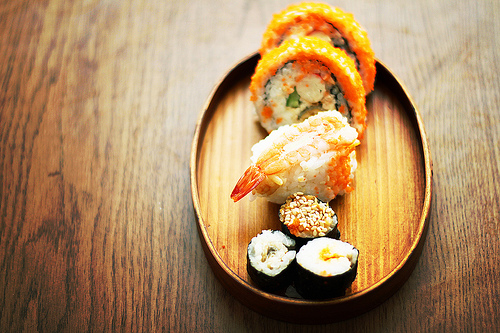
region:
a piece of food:
[287, 235, 389, 294]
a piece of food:
[245, 217, 305, 279]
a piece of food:
[278, 182, 353, 244]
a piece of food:
[227, 129, 330, 201]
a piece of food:
[303, 105, 360, 177]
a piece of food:
[251, 54, 316, 153]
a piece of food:
[308, 51, 379, 185]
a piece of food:
[237, 50, 305, 231]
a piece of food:
[284, 97, 349, 196]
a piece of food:
[233, 122, 313, 274]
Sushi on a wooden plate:
[209, 2, 415, 308]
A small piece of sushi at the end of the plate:
[298, 237, 358, 281]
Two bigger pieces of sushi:
[252, 0, 379, 127]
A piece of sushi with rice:
[276, 189, 334, 244]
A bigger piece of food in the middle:
[226, 109, 362, 215]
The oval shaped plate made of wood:
[187, 30, 428, 305]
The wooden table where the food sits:
[1, 1, 496, 331]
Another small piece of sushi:
[242, 224, 295, 281]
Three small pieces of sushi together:
[250, 191, 356, 281]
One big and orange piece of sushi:
[248, 39, 365, 137]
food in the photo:
[210, 27, 405, 282]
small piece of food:
[286, 227, 366, 297]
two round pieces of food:
[224, 226, 359, 296]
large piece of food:
[232, 114, 359, 192]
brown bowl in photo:
[363, 150, 438, 221]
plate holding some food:
[355, 152, 422, 215]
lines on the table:
[23, 162, 173, 268]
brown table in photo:
[37, 141, 165, 242]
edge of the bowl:
[159, 109, 223, 250]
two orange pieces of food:
[249, 9, 369, 115]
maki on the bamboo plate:
[237, 2, 382, 297]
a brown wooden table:
[24, 67, 165, 319]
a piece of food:
[233, 90, 367, 214]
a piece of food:
[284, 55, 386, 127]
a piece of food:
[282, 19, 405, 99]